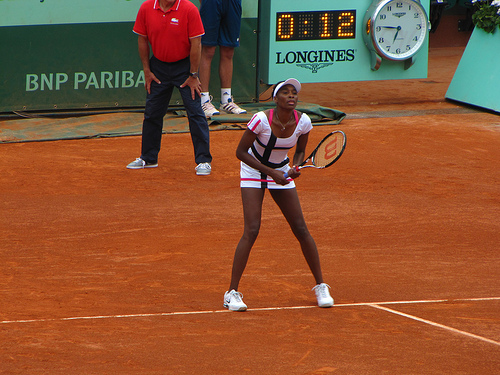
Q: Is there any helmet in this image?
A: No, there are no helmets.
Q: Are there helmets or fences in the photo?
A: No, there are no helmets or fences.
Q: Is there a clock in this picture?
A: Yes, there is a clock.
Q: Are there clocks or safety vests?
A: Yes, there is a clock.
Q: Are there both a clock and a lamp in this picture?
A: No, there is a clock but no lamps.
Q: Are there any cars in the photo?
A: No, there are no cars.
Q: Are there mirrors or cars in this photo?
A: No, there are no cars or mirrors.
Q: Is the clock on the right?
A: Yes, the clock is on the right of the image.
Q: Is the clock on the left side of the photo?
A: No, the clock is on the right of the image.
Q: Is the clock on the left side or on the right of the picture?
A: The clock is on the right of the image.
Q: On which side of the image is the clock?
A: The clock is on the right of the image.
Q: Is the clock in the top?
A: Yes, the clock is in the top of the image.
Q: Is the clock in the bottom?
A: No, the clock is in the top of the image.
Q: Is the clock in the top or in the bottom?
A: The clock is in the top of the image.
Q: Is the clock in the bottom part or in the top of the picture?
A: The clock is in the top of the image.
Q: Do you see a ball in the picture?
A: No, there are no balls.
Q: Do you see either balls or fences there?
A: No, there are no balls or fences.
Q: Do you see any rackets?
A: Yes, there is a racket.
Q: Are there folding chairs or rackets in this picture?
A: Yes, there is a racket.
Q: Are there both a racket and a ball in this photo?
A: No, there is a racket but no balls.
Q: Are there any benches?
A: No, there are no benches.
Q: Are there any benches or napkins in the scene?
A: No, there are no benches or napkins.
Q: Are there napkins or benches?
A: No, there are no benches or napkins.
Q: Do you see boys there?
A: No, there are no boys.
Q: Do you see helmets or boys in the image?
A: No, there are no boys or helmets.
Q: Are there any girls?
A: No, there are no girls.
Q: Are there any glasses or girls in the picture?
A: No, there are no girls or glasses.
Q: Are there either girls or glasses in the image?
A: No, there are no girls or glasses.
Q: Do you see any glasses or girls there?
A: No, there are no girls or glasses.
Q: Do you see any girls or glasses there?
A: No, there are no girls or glasses.